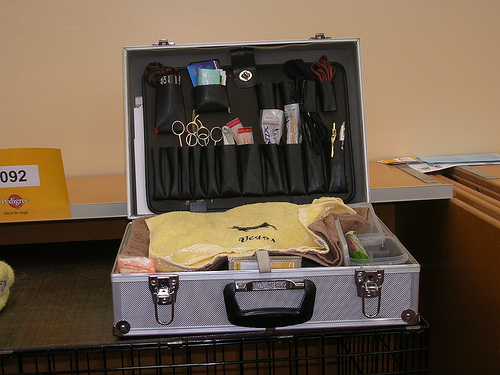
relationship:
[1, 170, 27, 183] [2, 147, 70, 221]
numbers on envelope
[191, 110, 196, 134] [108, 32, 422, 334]
scissors in briefcase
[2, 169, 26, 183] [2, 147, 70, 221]
092 on envelope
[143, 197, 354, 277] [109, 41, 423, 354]
towel inside case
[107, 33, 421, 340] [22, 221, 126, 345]
brief case on desk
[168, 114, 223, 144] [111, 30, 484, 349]
scissors in briefcase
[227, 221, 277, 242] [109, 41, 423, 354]
logo by case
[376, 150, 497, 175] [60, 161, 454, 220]
papers laying on desk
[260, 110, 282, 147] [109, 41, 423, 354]
cream in case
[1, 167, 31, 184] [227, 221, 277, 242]
numbers on logo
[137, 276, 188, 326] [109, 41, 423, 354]
latch on case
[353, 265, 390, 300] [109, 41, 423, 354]
latch on case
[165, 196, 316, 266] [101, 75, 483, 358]
contents in case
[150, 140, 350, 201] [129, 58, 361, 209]
pocket in case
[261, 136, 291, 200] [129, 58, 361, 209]
pocket in case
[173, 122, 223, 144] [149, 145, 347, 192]
handles sticking out of pocket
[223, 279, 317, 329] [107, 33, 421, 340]
handle of brief case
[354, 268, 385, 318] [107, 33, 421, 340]
latch of brief case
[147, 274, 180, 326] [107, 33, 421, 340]
latch of brief case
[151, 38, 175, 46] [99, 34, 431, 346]
latch of suitcase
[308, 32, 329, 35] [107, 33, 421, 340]
latch of brief case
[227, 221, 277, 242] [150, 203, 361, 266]
logo of towel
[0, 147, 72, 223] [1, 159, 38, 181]
envelope with number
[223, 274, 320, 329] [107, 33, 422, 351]
handle of brief case